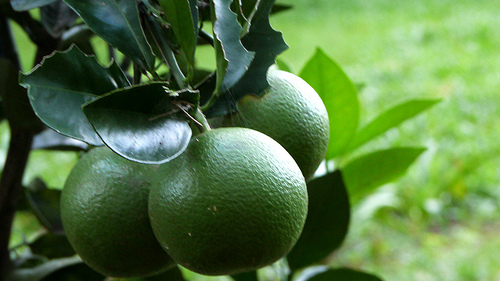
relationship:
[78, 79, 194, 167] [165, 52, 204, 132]
leaf on stem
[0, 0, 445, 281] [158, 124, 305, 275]
lime tree with limes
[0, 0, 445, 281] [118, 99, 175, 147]
lime tree with leaves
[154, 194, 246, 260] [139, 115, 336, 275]
imperfections on lime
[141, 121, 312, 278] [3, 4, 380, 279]
lime on tree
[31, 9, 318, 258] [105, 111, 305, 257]
lime tree with limes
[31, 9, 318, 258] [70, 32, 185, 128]
lime tree with leaves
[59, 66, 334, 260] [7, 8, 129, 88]
fruits are on branch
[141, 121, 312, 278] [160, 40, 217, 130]
lime hanging from branch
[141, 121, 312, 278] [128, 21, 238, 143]
lime hanging from branch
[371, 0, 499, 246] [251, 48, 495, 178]
plants in background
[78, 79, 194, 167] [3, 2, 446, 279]
leaf on plant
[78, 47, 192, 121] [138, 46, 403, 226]
leaf near plant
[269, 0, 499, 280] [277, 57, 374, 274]
ground beneath plant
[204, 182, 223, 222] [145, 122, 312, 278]
spot on fruit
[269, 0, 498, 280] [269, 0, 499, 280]
plants on ground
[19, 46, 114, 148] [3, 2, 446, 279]
leaf on plant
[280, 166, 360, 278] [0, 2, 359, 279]
leaf on plant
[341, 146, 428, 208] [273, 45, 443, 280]
leaf on plant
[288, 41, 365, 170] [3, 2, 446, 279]
leaf on plant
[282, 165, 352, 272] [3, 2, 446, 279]
leaf on plant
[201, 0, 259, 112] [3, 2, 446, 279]
leaf on plant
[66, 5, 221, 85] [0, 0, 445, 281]
leaf on lime tree